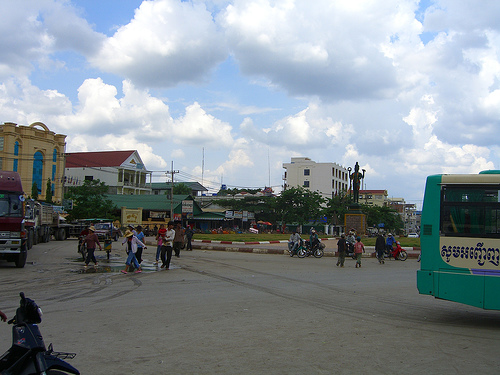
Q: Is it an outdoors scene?
A: Yes, it is outdoors.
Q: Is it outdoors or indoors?
A: It is outdoors.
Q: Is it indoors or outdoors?
A: It is outdoors.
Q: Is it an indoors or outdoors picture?
A: It is outdoors.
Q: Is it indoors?
A: No, it is outdoors.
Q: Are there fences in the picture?
A: No, there are no fences.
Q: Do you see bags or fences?
A: No, there are no fences or bags.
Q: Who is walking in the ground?
A: The people are walking in the ground.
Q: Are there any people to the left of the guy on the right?
A: Yes, there are people to the left of the guy.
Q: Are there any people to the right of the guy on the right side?
A: No, the people are to the left of the guy.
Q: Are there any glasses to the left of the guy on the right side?
A: No, there are people to the left of the guy.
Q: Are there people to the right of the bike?
A: Yes, there are people to the right of the bike.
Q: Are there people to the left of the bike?
A: No, the people are to the right of the bike.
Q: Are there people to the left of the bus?
A: Yes, there are people to the left of the bus.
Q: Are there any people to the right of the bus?
A: No, the people are to the left of the bus.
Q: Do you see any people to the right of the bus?
A: No, the people are to the left of the bus.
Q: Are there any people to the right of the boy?
A: Yes, there are people to the right of the boy.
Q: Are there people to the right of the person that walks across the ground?
A: Yes, there are people to the right of the boy.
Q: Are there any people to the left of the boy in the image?
A: No, the people are to the right of the boy.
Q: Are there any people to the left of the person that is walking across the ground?
A: No, the people are to the right of the boy.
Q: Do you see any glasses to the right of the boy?
A: No, there are people to the right of the boy.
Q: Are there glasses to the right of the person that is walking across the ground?
A: No, there are people to the right of the boy.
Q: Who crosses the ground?
A: The people cross the ground.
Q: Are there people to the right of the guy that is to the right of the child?
A: Yes, there are people to the right of the guy.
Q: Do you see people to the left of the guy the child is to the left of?
A: No, the people are to the right of the guy.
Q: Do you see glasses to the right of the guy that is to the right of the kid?
A: No, there are people to the right of the guy.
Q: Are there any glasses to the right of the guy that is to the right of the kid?
A: No, there are people to the right of the guy.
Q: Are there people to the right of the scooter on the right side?
A: No, the people are to the left of the scooter.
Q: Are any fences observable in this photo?
A: No, there are no fences.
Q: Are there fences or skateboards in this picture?
A: No, there are no fences or skateboards.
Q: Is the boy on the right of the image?
A: Yes, the boy is on the right of the image.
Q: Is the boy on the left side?
A: No, the boy is on the right of the image.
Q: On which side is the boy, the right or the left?
A: The boy is on the right of the image.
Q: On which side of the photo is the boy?
A: The boy is on the right of the image.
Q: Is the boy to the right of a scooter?
A: Yes, the boy is to the right of a scooter.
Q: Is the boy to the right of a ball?
A: No, the boy is to the right of a scooter.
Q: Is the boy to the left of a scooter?
A: No, the boy is to the right of a scooter.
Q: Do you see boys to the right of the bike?
A: Yes, there is a boy to the right of the bike.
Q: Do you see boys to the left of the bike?
A: No, the boy is to the right of the bike.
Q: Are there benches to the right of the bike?
A: No, there is a boy to the right of the bike.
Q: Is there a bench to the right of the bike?
A: No, there is a boy to the right of the bike.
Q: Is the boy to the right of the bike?
A: Yes, the boy is to the right of the bike.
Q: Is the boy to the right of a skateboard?
A: No, the boy is to the right of the bike.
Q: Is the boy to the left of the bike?
A: No, the boy is to the right of the bike.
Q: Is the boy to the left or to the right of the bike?
A: The boy is to the right of the bike.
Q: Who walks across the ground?
A: The boy walks across the ground.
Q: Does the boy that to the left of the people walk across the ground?
A: Yes, the boy walks across the ground.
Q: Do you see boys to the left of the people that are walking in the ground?
A: Yes, there is a boy to the left of the people.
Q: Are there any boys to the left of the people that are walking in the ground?
A: Yes, there is a boy to the left of the people.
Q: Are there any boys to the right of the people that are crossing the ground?
A: No, the boy is to the left of the people.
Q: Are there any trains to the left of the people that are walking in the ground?
A: No, there is a boy to the left of the people.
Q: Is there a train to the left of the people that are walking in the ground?
A: No, there is a boy to the left of the people.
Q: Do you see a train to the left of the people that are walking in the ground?
A: No, there is a boy to the left of the people.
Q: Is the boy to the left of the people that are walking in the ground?
A: Yes, the boy is to the left of the people.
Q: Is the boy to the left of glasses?
A: No, the boy is to the left of the people.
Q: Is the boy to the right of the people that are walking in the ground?
A: No, the boy is to the left of the people.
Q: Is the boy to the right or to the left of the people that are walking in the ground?
A: The boy is to the left of the people.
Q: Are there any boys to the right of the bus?
A: No, the boy is to the left of the bus.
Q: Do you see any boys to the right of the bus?
A: No, the boy is to the left of the bus.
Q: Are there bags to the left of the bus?
A: No, there is a boy to the left of the bus.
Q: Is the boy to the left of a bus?
A: Yes, the boy is to the left of a bus.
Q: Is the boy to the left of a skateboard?
A: No, the boy is to the left of a bus.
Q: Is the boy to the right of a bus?
A: No, the boy is to the left of a bus.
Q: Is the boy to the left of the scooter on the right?
A: Yes, the boy is to the left of the scooter.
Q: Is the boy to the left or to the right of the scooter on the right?
A: The boy is to the left of the scooter.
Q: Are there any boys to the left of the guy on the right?
A: Yes, there is a boy to the left of the guy.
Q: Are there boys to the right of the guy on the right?
A: No, the boy is to the left of the guy.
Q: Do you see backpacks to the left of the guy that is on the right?
A: No, there is a boy to the left of the guy.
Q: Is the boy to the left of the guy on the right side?
A: Yes, the boy is to the left of the guy.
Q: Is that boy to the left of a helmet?
A: No, the boy is to the left of the guy.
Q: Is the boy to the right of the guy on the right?
A: No, the boy is to the left of the guy.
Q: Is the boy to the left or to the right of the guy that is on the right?
A: The boy is to the left of the guy.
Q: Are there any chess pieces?
A: No, there are no chess pieces.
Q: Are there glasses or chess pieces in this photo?
A: No, there are no chess pieces or glasses.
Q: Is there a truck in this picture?
A: Yes, there is a truck.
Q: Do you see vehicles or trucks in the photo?
A: Yes, there is a truck.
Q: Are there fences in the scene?
A: No, there are no fences.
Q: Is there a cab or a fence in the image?
A: No, there are no fences or taxis.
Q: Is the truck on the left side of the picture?
A: Yes, the truck is on the left of the image.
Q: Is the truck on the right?
A: No, the truck is on the left of the image.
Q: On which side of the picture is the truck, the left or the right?
A: The truck is on the left of the image.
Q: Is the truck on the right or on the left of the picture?
A: The truck is on the left of the image.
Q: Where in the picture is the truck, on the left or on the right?
A: The truck is on the left of the image.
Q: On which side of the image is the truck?
A: The truck is on the left of the image.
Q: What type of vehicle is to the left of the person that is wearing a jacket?
A: The vehicle is a truck.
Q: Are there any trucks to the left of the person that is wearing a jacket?
A: Yes, there is a truck to the left of the person.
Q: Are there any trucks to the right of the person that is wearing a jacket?
A: No, the truck is to the left of the person.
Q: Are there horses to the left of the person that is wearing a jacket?
A: No, there is a truck to the left of the person.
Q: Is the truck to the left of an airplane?
A: No, the truck is to the left of a person.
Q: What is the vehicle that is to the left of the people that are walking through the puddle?
A: The vehicle is a truck.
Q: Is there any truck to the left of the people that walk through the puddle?
A: Yes, there is a truck to the left of the people.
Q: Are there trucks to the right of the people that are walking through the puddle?
A: No, the truck is to the left of the people.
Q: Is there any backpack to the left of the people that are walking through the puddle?
A: No, there is a truck to the left of the people.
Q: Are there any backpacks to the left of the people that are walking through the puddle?
A: No, there is a truck to the left of the people.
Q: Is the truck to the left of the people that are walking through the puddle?
A: Yes, the truck is to the left of the people.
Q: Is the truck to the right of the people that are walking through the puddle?
A: No, the truck is to the left of the people.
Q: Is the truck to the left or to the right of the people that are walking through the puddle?
A: The truck is to the left of the people.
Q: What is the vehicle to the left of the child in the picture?
A: The vehicle is a truck.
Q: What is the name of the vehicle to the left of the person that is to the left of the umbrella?
A: The vehicle is a truck.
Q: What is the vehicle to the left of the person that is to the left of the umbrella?
A: The vehicle is a truck.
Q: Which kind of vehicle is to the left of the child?
A: The vehicle is a truck.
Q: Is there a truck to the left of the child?
A: Yes, there is a truck to the left of the child.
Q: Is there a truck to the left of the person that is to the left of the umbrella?
A: Yes, there is a truck to the left of the child.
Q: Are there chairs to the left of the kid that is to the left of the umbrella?
A: No, there is a truck to the left of the child.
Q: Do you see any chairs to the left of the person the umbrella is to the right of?
A: No, there is a truck to the left of the child.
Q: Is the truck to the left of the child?
A: Yes, the truck is to the left of the child.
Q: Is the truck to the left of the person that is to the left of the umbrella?
A: Yes, the truck is to the left of the child.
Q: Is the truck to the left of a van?
A: No, the truck is to the left of the child.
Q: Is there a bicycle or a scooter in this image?
A: Yes, there is a scooter.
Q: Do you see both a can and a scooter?
A: No, there is a scooter but no cans.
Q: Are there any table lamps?
A: No, there are no table lamps.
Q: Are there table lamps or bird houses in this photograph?
A: No, there are no table lamps or bird houses.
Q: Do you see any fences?
A: No, there are no fences.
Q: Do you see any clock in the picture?
A: No, there are no clocks.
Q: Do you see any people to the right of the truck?
A: Yes, there is a person to the right of the truck.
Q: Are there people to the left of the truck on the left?
A: No, the person is to the right of the truck.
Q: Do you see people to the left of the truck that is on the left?
A: No, the person is to the right of the truck.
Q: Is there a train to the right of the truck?
A: No, there is a person to the right of the truck.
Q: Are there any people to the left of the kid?
A: Yes, there is a person to the left of the kid.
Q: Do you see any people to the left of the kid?
A: Yes, there is a person to the left of the kid.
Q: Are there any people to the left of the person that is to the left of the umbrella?
A: Yes, there is a person to the left of the kid.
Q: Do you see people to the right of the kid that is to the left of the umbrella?
A: No, the person is to the left of the child.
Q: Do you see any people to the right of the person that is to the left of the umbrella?
A: No, the person is to the left of the child.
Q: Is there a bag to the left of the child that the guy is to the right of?
A: No, there is a person to the left of the kid.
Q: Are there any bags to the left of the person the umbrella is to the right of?
A: No, there is a person to the left of the kid.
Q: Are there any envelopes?
A: No, there are no envelopes.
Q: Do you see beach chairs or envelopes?
A: No, there are no envelopes or beach chairs.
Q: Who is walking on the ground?
A: The couple is walking on the ground.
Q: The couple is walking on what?
A: The couple is walking on the ground.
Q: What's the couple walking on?
A: The couple is walking on the ground.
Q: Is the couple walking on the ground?
A: Yes, the couple is walking on the ground.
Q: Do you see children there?
A: Yes, there is a child.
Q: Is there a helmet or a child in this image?
A: Yes, there is a child.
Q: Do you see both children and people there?
A: Yes, there are both a child and a person.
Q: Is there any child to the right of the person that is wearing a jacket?
A: Yes, there is a child to the right of the person.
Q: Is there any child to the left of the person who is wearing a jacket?
A: No, the child is to the right of the person.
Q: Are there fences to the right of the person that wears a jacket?
A: No, there is a child to the right of the person.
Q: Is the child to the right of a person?
A: Yes, the child is to the right of a person.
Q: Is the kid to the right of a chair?
A: No, the kid is to the right of a person.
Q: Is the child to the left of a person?
A: No, the child is to the right of a person.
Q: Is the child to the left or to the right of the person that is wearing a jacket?
A: The child is to the right of the person.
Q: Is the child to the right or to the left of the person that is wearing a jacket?
A: The child is to the right of the person.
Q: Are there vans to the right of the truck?
A: No, there is a child to the right of the truck.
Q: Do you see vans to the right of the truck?
A: No, there is a child to the right of the truck.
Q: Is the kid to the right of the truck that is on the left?
A: Yes, the kid is to the right of the truck.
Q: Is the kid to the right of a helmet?
A: No, the kid is to the right of the truck.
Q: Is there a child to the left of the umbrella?
A: Yes, there is a child to the left of the umbrella.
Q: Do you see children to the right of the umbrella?
A: No, the child is to the left of the umbrella.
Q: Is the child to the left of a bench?
A: No, the child is to the left of the umbrella.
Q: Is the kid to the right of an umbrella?
A: No, the kid is to the left of an umbrella.